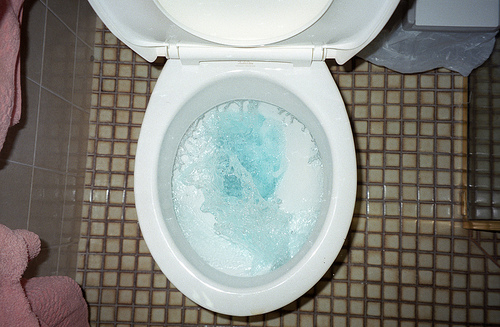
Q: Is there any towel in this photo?
A: Yes, there is a towel.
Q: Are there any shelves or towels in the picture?
A: Yes, there is a towel.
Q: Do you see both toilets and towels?
A: Yes, there are both a towel and a toilet.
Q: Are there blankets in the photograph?
A: No, there are no blankets.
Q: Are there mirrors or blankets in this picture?
A: No, there are no blankets or mirrors.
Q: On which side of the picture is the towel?
A: The towel is on the left of the image.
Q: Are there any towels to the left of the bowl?
A: Yes, there is a towel to the left of the bowl.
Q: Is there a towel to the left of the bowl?
A: Yes, there is a towel to the left of the bowl.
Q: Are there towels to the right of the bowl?
A: No, the towel is to the left of the bowl.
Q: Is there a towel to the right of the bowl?
A: No, the towel is to the left of the bowl.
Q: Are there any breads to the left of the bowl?
A: No, there is a towel to the left of the bowl.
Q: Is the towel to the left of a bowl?
A: Yes, the towel is to the left of a bowl.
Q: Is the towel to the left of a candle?
A: No, the towel is to the left of a bowl.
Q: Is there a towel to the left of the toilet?
A: Yes, there is a towel to the left of the toilet.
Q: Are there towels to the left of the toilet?
A: Yes, there is a towel to the left of the toilet.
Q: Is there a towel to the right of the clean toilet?
A: No, the towel is to the left of the toilet.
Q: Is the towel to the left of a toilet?
A: Yes, the towel is to the left of a toilet.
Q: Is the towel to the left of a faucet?
A: No, the towel is to the left of a toilet.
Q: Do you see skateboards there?
A: No, there are no skateboards.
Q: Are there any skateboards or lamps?
A: No, there are no skateboards or lamps.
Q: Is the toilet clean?
A: Yes, the toilet is clean.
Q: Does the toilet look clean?
A: Yes, the toilet is clean.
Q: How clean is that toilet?
A: The toilet is clean.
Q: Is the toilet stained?
A: No, the toilet is clean.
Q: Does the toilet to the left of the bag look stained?
A: No, the toilet is clean.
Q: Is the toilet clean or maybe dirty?
A: The toilet is clean.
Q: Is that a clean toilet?
A: Yes, that is a clean toilet.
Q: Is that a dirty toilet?
A: No, that is a clean toilet.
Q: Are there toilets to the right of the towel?
A: Yes, there is a toilet to the right of the towel.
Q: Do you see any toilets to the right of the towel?
A: Yes, there is a toilet to the right of the towel.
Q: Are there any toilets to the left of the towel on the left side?
A: No, the toilet is to the right of the towel.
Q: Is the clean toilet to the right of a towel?
A: Yes, the toilet is to the right of a towel.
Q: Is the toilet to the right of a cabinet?
A: No, the toilet is to the right of a towel.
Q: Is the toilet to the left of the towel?
A: No, the toilet is to the right of the towel.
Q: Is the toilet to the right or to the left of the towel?
A: The toilet is to the right of the towel.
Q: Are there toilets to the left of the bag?
A: Yes, there is a toilet to the left of the bag.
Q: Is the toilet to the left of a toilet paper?
A: No, the toilet is to the left of the bag.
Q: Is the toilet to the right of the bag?
A: No, the toilet is to the left of the bag.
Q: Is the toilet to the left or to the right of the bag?
A: The toilet is to the left of the bag.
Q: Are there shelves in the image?
A: No, there are no shelves.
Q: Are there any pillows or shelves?
A: No, there are no shelves or pillows.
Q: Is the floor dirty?
A: Yes, the floor is dirty.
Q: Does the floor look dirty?
A: Yes, the floor is dirty.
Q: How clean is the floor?
A: The floor is dirty.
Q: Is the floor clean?
A: No, the floor is dirty.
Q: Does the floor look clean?
A: No, the floor is dirty.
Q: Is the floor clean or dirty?
A: The floor is dirty.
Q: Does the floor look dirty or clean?
A: The floor is dirty.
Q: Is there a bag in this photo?
A: Yes, there is a bag.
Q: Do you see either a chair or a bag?
A: Yes, there is a bag.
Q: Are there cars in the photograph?
A: No, there are no cars.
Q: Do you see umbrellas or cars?
A: No, there are no cars or umbrellas.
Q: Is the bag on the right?
A: Yes, the bag is on the right of the image.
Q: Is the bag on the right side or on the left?
A: The bag is on the right of the image.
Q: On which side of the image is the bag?
A: The bag is on the right of the image.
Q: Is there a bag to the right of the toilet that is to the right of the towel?
A: Yes, there is a bag to the right of the toilet.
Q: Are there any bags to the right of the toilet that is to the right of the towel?
A: Yes, there is a bag to the right of the toilet.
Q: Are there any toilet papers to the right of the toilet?
A: No, there is a bag to the right of the toilet.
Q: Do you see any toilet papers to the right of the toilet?
A: No, there is a bag to the right of the toilet.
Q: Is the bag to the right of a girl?
A: No, the bag is to the right of the toilet.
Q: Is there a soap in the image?
A: No, there are no soaps.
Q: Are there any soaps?
A: No, there are no soaps.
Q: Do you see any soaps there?
A: No, there are no soaps.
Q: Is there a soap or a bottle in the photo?
A: No, there are no soaps or bottles.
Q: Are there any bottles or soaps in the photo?
A: No, there are no soaps or bottles.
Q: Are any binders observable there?
A: No, there are no binders.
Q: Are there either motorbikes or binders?
A: No, there are no binders or motorbikes.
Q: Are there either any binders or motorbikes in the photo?
A: No, there are no binders or motorbikes.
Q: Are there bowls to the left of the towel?
A: No, the bowl is to the right of the towel.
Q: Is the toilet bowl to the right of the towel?
A: Yes, the bowl is to the right of the towel.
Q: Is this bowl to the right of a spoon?
A: No, the bowl is to the right of the towel.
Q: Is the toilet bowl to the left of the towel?
A: No, the bowl is to the right of the towel.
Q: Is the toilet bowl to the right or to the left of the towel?
A: The bowl is to the right of the towel.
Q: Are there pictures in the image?
A: No, there are no pictures.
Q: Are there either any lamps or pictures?
A: No, there are no pictures or lamps.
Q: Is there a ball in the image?
A: No, there are no balls.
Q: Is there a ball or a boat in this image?
A: No, there are no balls or boats.